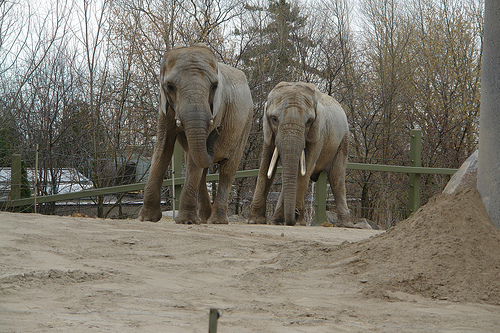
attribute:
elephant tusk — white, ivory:
[265, 148, 277, 179]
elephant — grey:
[251, 75, 346, 229]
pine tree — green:
[235, 2, 330, 97]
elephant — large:
[239, 55, 376, 232]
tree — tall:
[421, 25, 461, 118]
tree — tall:
[75, 32, 105, 129]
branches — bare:
[0, 0, 252, 220]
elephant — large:
[134, 40, 249, 231]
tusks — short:
[258, 138, 312, 181]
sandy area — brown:
[87, 240, 319, 274]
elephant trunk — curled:
[177, 103, 227, 172]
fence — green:
[363, 152, 417, 219]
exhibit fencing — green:
[58, 178, 118, 204]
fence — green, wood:
[2, 156, 459, 239]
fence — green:
[3, 158, 460, 214]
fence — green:
[7, 122, 458, 223]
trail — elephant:
[88, 226, 355, 326]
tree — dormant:
[58, 6, 147, 217]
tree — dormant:
[326, 7, 446, 227]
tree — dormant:
[378, 5, 481, 198]